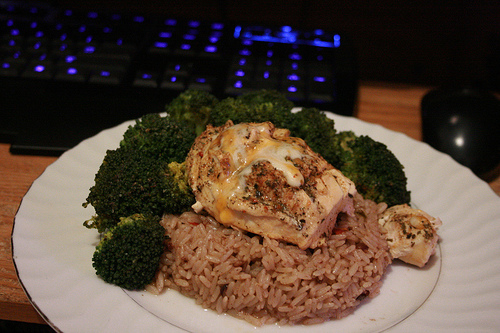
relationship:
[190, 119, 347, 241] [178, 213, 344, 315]
meat on rice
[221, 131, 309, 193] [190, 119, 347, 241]
cheese on meat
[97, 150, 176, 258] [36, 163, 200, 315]
broccoli on plate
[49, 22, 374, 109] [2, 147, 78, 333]
keyboard on table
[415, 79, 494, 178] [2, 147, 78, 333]
mouse on table